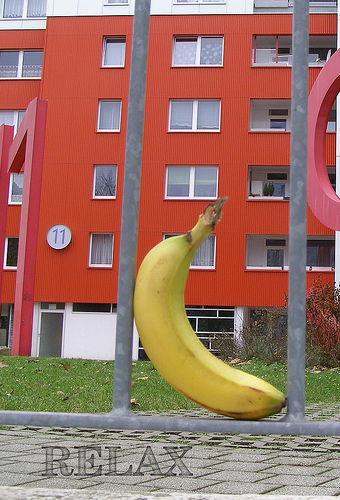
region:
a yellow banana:
[144, 182, 291, 418]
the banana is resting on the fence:
[127, 181, 305, 440]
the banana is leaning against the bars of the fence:
[110, 183, 301, 449]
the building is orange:
[41, 20, 337, 388]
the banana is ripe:
[133, 194, 301, 423]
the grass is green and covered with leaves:
[1, 351, 338, 410]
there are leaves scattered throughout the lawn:
[2, 356, 331, 423]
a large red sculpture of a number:
[5, 81, 80, 363]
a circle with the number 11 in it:
[38, 217, 89, 268]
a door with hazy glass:
[36, 304, 74, 362]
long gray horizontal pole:
[0, 409, 339, 437]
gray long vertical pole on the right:
[279, 0, 308, 421]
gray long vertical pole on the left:
[112, 1, 150, 412]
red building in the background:
[1, 16, 338, 358]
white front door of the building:
[29, 303, 71, 358]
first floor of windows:
[3, 232, 336, 271]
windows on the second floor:
[4, 164, 339, 204]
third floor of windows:
[2, 96, 338, 131]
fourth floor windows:
[0, 24, 337, 76]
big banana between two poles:
[133, 202, 286, 418]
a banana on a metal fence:
[127, 112, 300, 420]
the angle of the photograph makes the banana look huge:
[125, 63, 301, 423]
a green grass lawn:
[1, 354, 339, 422]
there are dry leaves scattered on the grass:
[2, 351, 339, 421]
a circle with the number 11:
[39, 220, 83, 253]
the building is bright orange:
[43, 17, 338, 356]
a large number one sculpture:
[0, 87, 63, 377]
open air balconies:
[248, 30, 339, 280]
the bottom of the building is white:
[21, 299, 307, 367]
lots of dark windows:
[139, 301, 244, 363]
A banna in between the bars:
[130, 181, 285, 422]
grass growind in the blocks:
[45, 423, 339, 452]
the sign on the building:
[45, 223, 76, 263]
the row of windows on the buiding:
[161, 54, 229, 204]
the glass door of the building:
[37, 307, 65, 358]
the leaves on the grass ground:
[0, 356, 92, 403]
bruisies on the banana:
[188, 370, 271, 418]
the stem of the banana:
[182, 196, 224, 252]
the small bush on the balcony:
[259, 180, 276, 195]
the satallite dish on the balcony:
[313, 43, 332, 66]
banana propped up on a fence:
[130, 196, 289, 418]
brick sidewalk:
[194, 450, 330, 493]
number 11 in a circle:
[46, 223, 73, 248]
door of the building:
[36, 310, 65, 356]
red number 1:
[4, 95, 50, 356]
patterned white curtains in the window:
[175, 36, 220, 66]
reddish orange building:
[52, 19, 120, 219]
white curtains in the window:
[170, 96, 219, 131]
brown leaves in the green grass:
[4, 358, 108, 405]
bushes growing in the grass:
[238, 306, 278, 374]